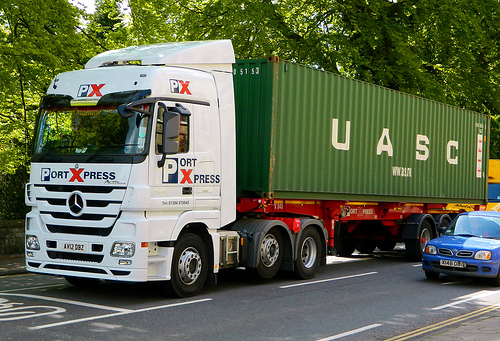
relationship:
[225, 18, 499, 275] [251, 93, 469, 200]
trailer on truck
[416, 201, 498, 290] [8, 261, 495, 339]
car on road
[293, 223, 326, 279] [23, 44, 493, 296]
tire in front of truck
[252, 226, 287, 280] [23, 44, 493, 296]
tire in front of truck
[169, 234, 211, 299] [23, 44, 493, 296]
tire in front of truck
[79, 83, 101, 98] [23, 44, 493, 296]
letters on top of truck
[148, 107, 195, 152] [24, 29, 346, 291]
sidemirror on truck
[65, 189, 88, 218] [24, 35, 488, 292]
emblen of trailer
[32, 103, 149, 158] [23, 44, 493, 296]
window on truck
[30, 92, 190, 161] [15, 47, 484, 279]
windshield on truck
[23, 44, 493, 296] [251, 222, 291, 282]
truck has tire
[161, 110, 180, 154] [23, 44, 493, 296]
mirror on truck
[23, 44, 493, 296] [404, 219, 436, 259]
truck has tire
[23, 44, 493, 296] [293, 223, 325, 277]
truck has tire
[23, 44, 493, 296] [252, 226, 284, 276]
truck has tire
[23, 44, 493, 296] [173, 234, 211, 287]
truck has tire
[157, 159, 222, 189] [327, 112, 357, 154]
port xpress on logo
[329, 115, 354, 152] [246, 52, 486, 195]
u on trailer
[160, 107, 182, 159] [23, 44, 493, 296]
side mirror on truck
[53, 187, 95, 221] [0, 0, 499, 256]
emblen on trees